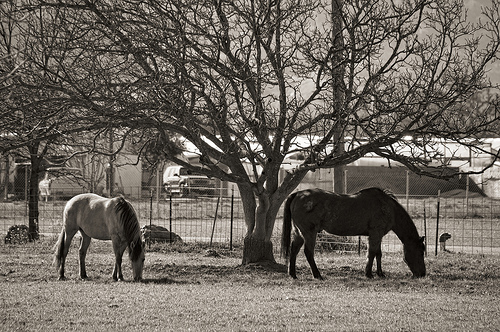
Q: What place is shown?
A: It is a meadow.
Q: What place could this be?
A: It is a meadow.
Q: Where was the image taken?
A: It was taken at the meadow.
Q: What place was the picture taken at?
A: It was taken at the meadow.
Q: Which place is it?
A: It is a meadow.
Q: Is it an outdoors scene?
A: Yes, it is outdoors.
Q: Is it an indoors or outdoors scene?
A: It is outdoors.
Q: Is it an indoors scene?
A: No, it is outdoors.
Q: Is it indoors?
A: No, it is outdoors.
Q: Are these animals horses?
A: Yes, all the animals are horses.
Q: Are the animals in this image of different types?
A: No, all the animals are horses.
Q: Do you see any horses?
A: Yes, there is a horse.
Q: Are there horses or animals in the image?
A: Yes, there is a horse.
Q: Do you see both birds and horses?
A: No, there is a horse but no birds.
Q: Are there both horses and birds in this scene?
A: No, there is a horse but no birds.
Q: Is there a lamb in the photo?
A: No, there are no lambs.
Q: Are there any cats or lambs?
A: No, there are no lambs or cats.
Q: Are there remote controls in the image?
A: Yes, there is a remote control.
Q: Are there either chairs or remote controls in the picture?
A: Yes, there is a remote control.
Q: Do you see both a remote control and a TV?
A: No, there is a remote control but no televisions.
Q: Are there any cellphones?
A: No, there are no cellphones.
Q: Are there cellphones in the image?
A: No, there are no cellphones.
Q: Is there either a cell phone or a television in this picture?
A: No, there are no cell phones or televisions.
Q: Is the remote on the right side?
A: Yes, the remote is on the right of the image.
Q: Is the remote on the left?
A: No, the remote is on the right of the image.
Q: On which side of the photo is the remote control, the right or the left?
A: The remote control is on the right of the image.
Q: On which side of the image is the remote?
A: The remote is on the right of the image.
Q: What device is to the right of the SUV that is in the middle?
A: The device is a remote control.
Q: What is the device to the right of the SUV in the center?
A: The device is a remote control.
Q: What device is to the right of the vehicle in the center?
A: The device is a remote control.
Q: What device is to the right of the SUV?
A: The device is a remote control.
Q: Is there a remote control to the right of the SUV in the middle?
A: Yes, there is a remote control to the right of the SUV.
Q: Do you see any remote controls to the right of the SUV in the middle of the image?
A: Yes, there is a remote control to the right of the SUV.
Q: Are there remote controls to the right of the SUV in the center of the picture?
A: Yes, there is a remote control to the right of the SUV.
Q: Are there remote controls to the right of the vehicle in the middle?
A: Yes, there is a remote control to the right of the SUV.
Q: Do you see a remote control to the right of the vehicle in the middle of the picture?
A: Yes, there is a remote control to the right of the SUV.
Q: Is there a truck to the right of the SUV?
A: No, there is a remote control to the right of the SUV.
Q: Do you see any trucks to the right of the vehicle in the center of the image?
A: No, there is a remote control to the right of the SUV.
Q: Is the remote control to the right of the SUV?
A: Yes, the remote control is to the right of the SUV.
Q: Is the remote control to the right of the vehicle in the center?
A: Yes, the remote control is to the right of the SUV.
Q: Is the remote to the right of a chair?
A: No, the remote is to the right of the SUV.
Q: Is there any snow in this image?
A: Yes, there is snow.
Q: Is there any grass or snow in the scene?
A: Yes, there is snow.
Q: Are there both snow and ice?
A: No, there is snow but no ice.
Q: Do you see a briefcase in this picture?
A: No, there are no briefcases.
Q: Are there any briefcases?
A: No, there are no briefcases.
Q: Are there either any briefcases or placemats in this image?
A: No, there are no briefcases or placemats.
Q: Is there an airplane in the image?
A: No, there are no airplanes.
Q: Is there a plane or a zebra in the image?
A: No, there are no airplanes or zebras.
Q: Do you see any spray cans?
A: No, there are no spray cans.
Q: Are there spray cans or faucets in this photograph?
A: No, there are no spray cans or faucets.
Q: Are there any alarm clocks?
A: No, there are no alarm clocks.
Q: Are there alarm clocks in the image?
A: No, there are no alarm clocks.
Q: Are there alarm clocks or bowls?
A: No, there are no alarm clocks or bowls.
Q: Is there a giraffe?
A: No, there are no giraffes.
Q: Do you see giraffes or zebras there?
A: No, there are no giraffes or zebras.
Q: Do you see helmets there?
A: No, there are no helmets.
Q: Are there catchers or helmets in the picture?
A: No, there are no helmets or catchers.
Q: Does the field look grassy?
A: Yes, the field is grassy.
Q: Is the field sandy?
A: No, the field is grassy.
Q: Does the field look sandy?
A: No, the field is grassy.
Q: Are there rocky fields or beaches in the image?
A: No, there is a field but it is grassy.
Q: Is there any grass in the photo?
A: Yes, there is grass.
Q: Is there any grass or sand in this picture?
A: Yes, there is grass.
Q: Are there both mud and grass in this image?
A: No, there is grass but no mud.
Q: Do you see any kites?
A: No, there are no kites.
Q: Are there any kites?
A: No, there are no kites.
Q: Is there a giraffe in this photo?
A: No, there are no giraffes.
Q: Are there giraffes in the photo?
A: No, there are no giraffes.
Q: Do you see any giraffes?
A: No, there are no giraffes.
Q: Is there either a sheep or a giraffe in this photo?
A: No, there are no giraffes or sheep.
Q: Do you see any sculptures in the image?
A: No, there are no sculptures.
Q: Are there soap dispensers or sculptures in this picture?
A: No, there are no sculptures or soap dispensers.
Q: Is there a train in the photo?
A: No, there are no trains.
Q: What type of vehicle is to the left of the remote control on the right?
A: The vehicle is a SUV.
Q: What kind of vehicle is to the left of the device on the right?
A: The vehicle is a SUV.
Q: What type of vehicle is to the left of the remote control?
A: The vehicle is a SUV.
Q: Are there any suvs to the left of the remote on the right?
A: Yes, there is a SUV to the left of the remote control.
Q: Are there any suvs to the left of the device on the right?
A: Yes, there is a SUV to the left of the remote control.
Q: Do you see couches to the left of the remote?
A: No, there is a SUV to the left of the remote.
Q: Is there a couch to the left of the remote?
A: No, there is a SUV to the left of the remote.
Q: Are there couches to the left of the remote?
A: No, there is a SUV to the left of the remote.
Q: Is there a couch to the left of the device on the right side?
A: No, there is a SUV to the left of the remote.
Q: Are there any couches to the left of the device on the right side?
A: No, there is a SUV to the left of the remote.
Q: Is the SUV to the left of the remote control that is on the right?
A: Yes, the SUV is to the left of the remote control.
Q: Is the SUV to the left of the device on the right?
A: Yes, the SUV is to the left of the remote control.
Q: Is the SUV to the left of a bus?
A: No, the SUV is to the left of the remote control.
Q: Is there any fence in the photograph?
A: Yes, there is a fence.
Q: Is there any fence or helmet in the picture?
A: Yes, there is a fence.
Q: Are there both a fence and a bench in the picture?
A: No, there is a fence but no benches.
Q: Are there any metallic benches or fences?
A: Yes, there is a metal fence.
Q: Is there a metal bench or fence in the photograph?
A: Yes, there is a metal fence.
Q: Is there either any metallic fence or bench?
A: Yes, there is a metal fence.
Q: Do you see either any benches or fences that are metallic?
A: Yes, the fence is metallic.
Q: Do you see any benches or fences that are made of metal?
A: Yes, the fence is made of metal.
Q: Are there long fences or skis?
A: Yes, there is a long fence.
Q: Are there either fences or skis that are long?
A: Yes, the fence is long.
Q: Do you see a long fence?
A: Yes, there is a long fence.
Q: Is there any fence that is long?
A: Yes, there is a fence that is long.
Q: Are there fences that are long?
A: Yes, there is a fence that is long.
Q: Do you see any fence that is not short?
A: Yes, there is a long fence.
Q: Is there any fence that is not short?
A: Yes, there is a long fence.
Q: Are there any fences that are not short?
A: Yes, there is a long fence.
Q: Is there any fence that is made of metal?
A: Yes, there is a fence that is made of metal.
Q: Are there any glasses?
A: No, there are no glasses.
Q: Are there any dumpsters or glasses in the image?
A: No, there are no glasses or dumpsters.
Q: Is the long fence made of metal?
A: Yes, the fence is made of metal.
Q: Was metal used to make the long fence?
A: Yes, the fence is made of metal.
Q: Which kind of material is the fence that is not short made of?
A: The fence is made of metal.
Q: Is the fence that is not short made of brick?
A: No, the fence is made of metal.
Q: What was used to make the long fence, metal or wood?
A: The fence is made of metal.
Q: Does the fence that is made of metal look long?
A: Yes, the fence is long.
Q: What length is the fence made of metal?
A: The fence is long.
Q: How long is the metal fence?
A: The fence is long.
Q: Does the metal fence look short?
A: No, the fence is long.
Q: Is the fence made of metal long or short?
A: The fence is long.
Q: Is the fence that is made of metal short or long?
A: The fence is long.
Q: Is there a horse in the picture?
A: Yes, there is a horse.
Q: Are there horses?
A: Yes, there is a horse.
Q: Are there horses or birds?
A: Yes, there is a horse.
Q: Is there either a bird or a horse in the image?
A: Yes, there is a horse.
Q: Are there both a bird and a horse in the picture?
A: No, there is a horse but no birds.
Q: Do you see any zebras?
A: No, there are no zebras.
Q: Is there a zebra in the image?
A: No, there are no zebras.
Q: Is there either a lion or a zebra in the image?
A: No, there are no zebras or lions.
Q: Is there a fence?
A: Yes, there is a fence.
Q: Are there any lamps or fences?
A: Yes, there is a fence.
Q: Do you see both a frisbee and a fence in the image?
A: No, there is a fence but no frisbees.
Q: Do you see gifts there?
A: No, there are no gifts.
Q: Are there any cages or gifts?
A: No, there are no gifts or cages.